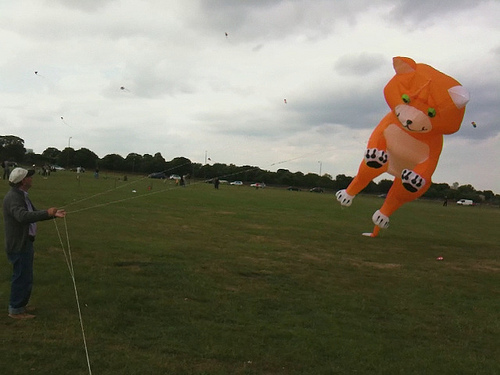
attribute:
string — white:
[53, 127, 325, 372]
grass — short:
[0, 162, 499, 373]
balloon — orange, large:
[332, 36, 471, 242]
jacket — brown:
[4, 187, 57, 258]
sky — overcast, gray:
[0, 2, 499, 194]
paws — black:
[362, 145, 425, 194]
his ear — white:
[449, 81, 471, 110]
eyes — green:
[398, 88, 438, 119]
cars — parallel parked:
[147, 167, 272, 191]